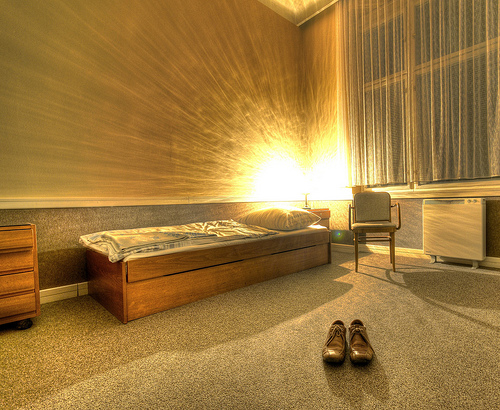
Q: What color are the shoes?
A: Brown.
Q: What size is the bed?
A: A twin.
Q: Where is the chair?
A: Near the window.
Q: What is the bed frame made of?
A: Wood.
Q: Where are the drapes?
A: In front of the window.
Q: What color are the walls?
A: Cream.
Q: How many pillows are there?
A: One.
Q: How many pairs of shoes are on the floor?
A: One.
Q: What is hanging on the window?
A: Curtains.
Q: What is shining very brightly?
A: A lamp.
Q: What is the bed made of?
A: Wood.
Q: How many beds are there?
A: One.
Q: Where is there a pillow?
A: The bed.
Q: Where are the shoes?
A: Carpet.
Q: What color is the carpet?
A: Grey.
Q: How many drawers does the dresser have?
A: Four.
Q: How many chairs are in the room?
A: One.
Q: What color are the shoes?
A: Brown.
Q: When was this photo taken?
A: At night.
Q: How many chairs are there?
A: 1.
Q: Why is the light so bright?
A: There is no lampshade on the lamp.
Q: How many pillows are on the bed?
A: 1.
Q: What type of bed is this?
A: A captain bed.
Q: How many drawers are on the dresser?
A: 4.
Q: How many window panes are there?
A: 4.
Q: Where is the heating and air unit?
A: Under the window.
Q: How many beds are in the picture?
A: One.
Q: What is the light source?
A: A lamp.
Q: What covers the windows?
A: Curtains.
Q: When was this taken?
A: Night time.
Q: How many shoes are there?
A: Two.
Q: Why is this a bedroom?
A: There is a bed in it.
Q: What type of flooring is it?
A: Carpet.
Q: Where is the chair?
A: Beside the bed.